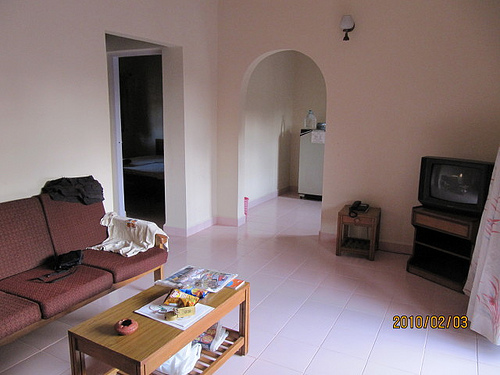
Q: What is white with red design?
A: The drapes.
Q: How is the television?
A: Off.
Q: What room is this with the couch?
A: Living room.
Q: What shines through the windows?
A: Light.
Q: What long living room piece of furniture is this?
A: Couch.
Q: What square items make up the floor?
A: Tiles.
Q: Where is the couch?
A: Living room.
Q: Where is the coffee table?
A: Living room.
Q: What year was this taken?
A: 2010.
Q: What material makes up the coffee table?
A: Wood.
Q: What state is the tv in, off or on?
A: Off.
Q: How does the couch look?
A: Cheap.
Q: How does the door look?
A: Big.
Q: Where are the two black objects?
A: On sofa.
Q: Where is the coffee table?
A: In front of couch.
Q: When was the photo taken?
A: Daylight.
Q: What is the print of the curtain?
A: Floral.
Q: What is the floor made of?
A: Tiles.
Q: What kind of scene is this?
A: Indoor.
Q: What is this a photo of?
A: Living room.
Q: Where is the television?
A: Near the wall.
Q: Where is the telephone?
A: On the chest.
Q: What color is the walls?
A: White.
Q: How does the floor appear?
A: Clean.